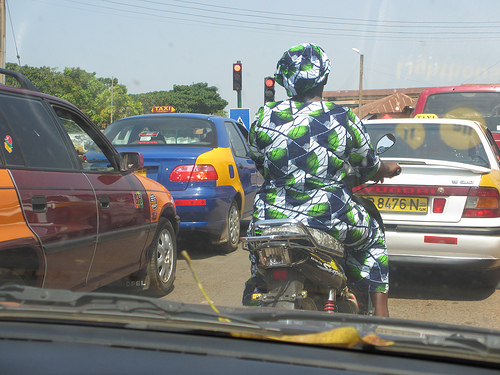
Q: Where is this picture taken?
A: On a road.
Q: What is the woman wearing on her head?
A: A scarf.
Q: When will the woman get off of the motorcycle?
A: After she has reached her destination.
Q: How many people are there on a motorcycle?
A: One.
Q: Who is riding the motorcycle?
A: A woman.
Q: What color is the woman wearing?
A: White, blue and green.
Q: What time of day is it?
A: Daytime.